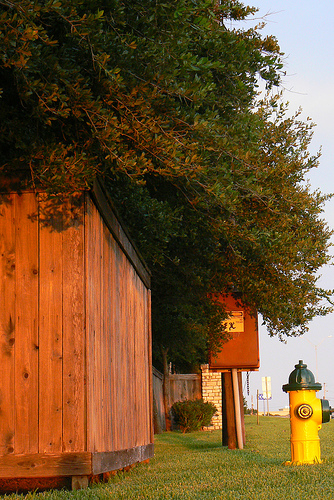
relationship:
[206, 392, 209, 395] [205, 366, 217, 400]
brick in pillar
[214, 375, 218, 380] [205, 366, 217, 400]
brick in pillar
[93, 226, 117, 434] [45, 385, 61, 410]
fence made of wood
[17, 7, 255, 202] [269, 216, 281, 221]
tree has leaf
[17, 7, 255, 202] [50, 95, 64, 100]
tree has leaf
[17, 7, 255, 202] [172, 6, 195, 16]
tree has leaf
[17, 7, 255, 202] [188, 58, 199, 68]
tree has leaf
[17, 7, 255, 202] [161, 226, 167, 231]
tree has leaf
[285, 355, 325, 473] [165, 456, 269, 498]
hydrant in grass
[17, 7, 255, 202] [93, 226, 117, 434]
tree over fence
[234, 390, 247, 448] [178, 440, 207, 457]
pole in ground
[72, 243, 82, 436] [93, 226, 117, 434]
panel in fence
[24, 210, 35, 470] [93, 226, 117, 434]
panel in fence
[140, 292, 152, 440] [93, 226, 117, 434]
panel in fence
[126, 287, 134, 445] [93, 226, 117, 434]
panel in fence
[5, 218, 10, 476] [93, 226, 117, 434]
panel in fence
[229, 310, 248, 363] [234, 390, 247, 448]
power box on pole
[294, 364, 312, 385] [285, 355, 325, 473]
top of hydrant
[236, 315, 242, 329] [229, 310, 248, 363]
sticker on power box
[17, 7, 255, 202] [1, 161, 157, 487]
tree covering building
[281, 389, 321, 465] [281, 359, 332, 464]
yellow base of hydrant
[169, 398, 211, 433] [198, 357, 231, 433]
bush by structure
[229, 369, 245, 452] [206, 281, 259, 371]
wooden post next to metal sign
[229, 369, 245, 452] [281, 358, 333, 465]
wooden post next to fire hydrant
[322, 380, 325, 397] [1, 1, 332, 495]
pole right side of photo